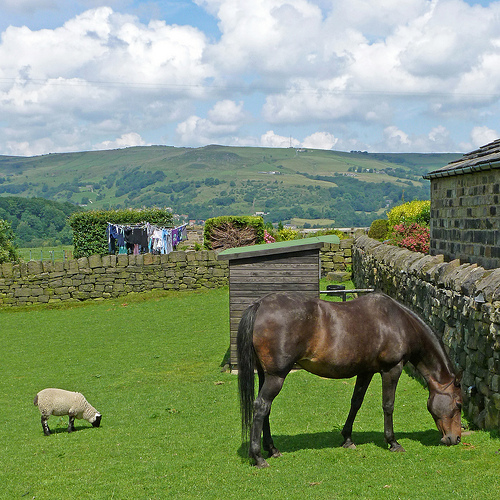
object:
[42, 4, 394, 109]
clouds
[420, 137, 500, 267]
house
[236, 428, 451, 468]
shadow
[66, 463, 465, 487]
ground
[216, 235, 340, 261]
roof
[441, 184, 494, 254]
wall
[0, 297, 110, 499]
grass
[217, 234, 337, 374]
wooden shed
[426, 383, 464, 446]
head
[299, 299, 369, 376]
body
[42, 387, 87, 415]
body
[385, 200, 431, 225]
flowers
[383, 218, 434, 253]
flowers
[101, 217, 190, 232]
clothes line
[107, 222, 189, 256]
clothes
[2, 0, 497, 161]
sky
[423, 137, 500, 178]
roof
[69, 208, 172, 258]
tree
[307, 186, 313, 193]
tree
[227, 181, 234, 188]
tree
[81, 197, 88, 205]
tree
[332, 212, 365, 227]
tree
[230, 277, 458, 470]
horse field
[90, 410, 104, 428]
head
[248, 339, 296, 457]
leg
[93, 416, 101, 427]
face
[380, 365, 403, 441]
legs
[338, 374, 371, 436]
legs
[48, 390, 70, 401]
wool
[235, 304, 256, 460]
tail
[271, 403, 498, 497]
grass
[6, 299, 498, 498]
field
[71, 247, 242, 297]
wall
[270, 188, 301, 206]
shrubs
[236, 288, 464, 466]
animal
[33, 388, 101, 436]
animal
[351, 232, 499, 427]
wall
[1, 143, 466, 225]
mountains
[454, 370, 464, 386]
ear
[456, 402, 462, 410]
eye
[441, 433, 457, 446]
mouth